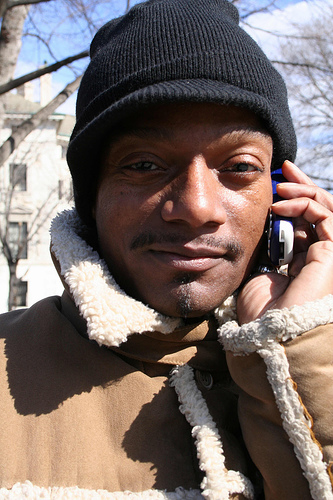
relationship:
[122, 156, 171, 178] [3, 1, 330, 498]
eye of man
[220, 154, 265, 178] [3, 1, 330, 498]
eye of man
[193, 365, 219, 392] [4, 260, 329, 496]
button on coat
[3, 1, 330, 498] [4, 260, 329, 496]
man has coat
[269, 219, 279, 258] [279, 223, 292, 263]
blue and white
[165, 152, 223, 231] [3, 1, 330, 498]
nose of man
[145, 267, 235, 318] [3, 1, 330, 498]
beard of man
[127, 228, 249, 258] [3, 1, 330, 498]
mustache of man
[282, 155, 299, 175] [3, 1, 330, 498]
fingernail of man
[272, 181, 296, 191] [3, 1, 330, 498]
fingernail of man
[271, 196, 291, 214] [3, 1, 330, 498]
fingernail of man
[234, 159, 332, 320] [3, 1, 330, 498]
hand of man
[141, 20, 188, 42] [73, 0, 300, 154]
black stocking cap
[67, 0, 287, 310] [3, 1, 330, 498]
head of man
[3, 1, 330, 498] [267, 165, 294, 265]
man on phone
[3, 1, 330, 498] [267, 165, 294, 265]
man holding phone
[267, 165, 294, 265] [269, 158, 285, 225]
phone to ear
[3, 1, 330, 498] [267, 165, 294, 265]
person holding phone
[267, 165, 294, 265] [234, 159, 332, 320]
phone in hand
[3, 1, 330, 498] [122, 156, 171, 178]
person's right eye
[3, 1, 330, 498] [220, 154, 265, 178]
person's left eye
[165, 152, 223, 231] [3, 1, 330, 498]
nose of person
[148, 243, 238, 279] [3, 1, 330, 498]
mouth of person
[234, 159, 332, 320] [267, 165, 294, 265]
hand holding phone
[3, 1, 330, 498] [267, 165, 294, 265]
man on cellphone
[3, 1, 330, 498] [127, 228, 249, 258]
man has mustache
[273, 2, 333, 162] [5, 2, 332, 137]
trees in background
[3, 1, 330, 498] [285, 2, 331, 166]
picture in daytime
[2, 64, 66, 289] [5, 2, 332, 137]
building in background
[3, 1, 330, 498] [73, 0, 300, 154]
man wearing cap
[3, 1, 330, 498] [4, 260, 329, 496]
man wearing coat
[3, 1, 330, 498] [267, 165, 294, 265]
man holds cellphone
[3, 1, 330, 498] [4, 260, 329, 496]
man wears jacket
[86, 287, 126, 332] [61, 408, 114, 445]
white and brown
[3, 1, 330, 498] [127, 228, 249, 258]
man has hair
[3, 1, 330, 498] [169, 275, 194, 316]
man has hair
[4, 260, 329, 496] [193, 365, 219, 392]
jacket has button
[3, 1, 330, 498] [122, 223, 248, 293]
man has smirk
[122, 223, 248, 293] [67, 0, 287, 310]
smirk on face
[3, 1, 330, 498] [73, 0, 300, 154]
man has hat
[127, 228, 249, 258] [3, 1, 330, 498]
mustache on man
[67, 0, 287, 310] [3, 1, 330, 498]
face of man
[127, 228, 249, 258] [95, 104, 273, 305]
mustache on face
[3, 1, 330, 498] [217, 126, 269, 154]
man's left eyebrow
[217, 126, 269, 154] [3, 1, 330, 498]
eyebrow of man's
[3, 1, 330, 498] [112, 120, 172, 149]
man's right eyebrow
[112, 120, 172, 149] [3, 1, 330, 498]
eyebrow of man's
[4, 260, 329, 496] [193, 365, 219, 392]
coat top button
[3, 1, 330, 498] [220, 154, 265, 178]
man's left eye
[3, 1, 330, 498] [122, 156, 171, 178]
man's right eye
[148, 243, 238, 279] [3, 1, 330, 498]
lips of man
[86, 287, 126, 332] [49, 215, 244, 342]
white wool collar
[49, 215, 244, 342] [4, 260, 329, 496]
collar of coat